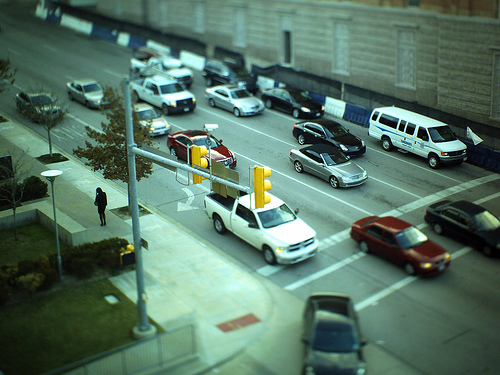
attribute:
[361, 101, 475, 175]
van — large